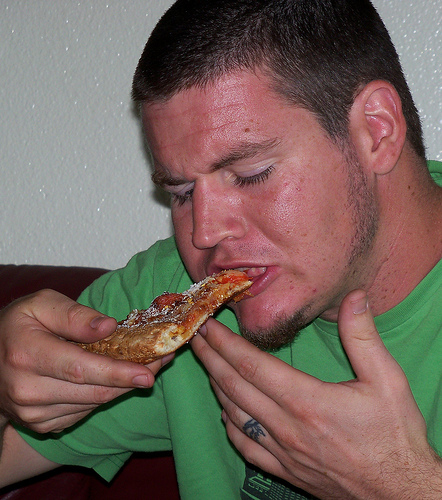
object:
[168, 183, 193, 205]
eye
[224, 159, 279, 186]
eye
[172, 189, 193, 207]
eyelashes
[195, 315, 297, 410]
finger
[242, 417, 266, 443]
tattoo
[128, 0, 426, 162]
hair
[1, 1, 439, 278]
wall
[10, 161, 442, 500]
green shirt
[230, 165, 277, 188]
eye lashes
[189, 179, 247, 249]
nose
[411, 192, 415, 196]
freckle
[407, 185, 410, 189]
freckle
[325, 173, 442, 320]
neck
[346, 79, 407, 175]
ear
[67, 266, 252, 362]
pizza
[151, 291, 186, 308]
pepperoni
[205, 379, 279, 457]
finger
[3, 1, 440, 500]
man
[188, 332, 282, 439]
finger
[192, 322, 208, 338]
finger nail